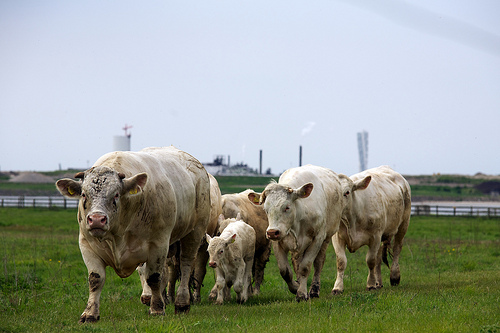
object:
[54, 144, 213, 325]
cow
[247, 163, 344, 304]
cow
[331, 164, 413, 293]
cow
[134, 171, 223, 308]
cow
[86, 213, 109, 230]
nose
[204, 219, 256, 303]
cow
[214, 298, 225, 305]
foot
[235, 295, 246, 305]
foot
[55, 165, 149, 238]
head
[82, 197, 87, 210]
spot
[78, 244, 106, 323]
leg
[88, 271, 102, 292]
spot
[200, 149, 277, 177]
building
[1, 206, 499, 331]
field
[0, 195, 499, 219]
fence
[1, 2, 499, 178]
sky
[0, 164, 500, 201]
grass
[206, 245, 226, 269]
face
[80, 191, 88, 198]
eye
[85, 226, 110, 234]
mouth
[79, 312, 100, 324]
hoof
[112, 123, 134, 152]
silo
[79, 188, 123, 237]
face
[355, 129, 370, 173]
tower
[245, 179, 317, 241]
herd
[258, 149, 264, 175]
smoke stack